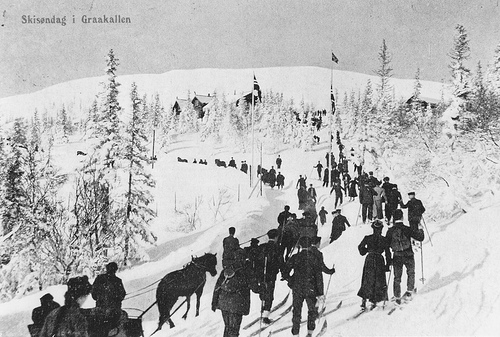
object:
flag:
[253, 75, 263, 102]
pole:
[252, 93, 254, 202]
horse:
[156, 252, 216, 327]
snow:
[5, 65, 499, 117]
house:
[172, 95, 219, 122]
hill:
[0, 65, 498, 154]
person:
[287, 236, 328, 336]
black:
[285, 250, 325, 298]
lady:
[359, 220, 391, 314]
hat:
[373, 219, 385, 230]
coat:
[213, 267, 267, 310]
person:
[212, 249, 266, 336]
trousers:
[291, 285, 317, 331]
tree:
[111, 82, 159, 268]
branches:
[129, 168, 152, 178]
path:
[141, 187, 290, 300]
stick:
[320, 263, 336, 319]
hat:
[299, 236, 312, 248]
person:
[403, 191, 426, 228]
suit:
[401, 198, 426, 229]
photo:
[1, 2, 499, 335]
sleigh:
[48, 297, 133, 336]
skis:
[281, 321, 332, 337]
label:
[22, 13, 131, 24]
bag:
[218, 268, 238, 293]